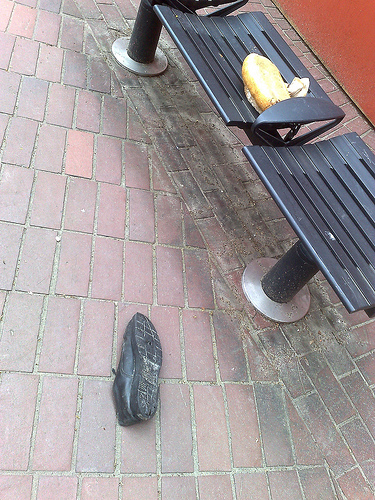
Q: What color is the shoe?
A: Black.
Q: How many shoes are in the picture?
A: One.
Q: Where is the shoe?
A: On the ground.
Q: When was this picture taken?
A: Daytime.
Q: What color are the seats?
A: Black.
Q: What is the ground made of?
A: Bricks.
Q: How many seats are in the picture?
A: Two.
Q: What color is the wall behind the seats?
A: Red.